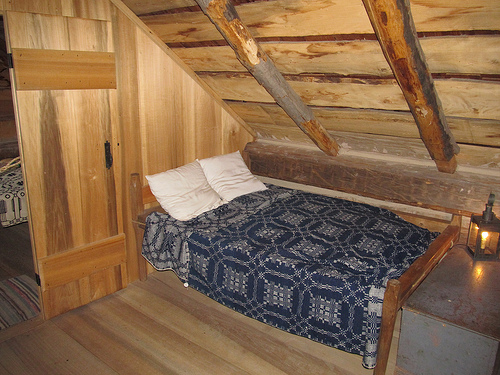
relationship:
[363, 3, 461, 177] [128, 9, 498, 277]
exposed log on wall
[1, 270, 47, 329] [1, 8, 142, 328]
rug behind door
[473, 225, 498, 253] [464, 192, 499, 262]
bulb inside bulb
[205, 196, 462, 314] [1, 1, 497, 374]
bed standing in bedroom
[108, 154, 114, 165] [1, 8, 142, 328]
knob mounted on door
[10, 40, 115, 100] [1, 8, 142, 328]
wood mounted on door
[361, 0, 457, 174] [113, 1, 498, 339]
exposed log holding up wall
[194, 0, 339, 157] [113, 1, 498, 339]
log holding up wall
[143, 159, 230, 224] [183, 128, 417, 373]
pillow lying on top of bed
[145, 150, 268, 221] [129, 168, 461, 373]
pillow lying on top of bed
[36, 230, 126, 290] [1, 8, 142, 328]
support holding up door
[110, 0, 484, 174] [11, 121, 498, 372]
roof covering bedroom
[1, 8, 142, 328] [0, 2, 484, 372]
door leading to bedroom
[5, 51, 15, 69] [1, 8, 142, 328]
hinge mounted on door